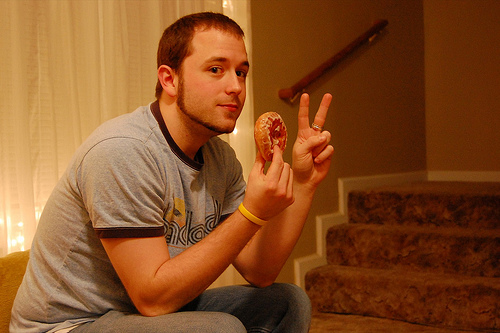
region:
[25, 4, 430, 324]
Man holding a donut.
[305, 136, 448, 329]
Stairs in the background.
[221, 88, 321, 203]
Donut in man's hands.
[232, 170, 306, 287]
Wrist band on man's arm.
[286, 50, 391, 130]
Railing on the wall.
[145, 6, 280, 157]
Man with facial hair.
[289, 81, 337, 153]
Ring on man's finger.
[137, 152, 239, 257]
Design on t-shirt.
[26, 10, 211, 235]
White curtains in the background.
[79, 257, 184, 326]
Denim on the man.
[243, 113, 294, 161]
Frosted donut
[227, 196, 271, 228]
Yellow rubber bracelet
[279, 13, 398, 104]
Wooden stair railing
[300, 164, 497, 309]
Brown patterned ascending stairs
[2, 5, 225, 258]
White curtain over window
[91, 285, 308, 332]
Light blue jeans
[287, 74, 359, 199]
Man's hand in a peace sign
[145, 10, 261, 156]
Man's head with brown hair and a beard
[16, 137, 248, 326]
Light blue shirt with dark blue edges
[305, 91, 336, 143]
Finger with a silver ring on it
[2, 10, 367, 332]
a man eating a doughnut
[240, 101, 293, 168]
the doughnut is brown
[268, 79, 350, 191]
the man is giving the peace sign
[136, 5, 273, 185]
the man has brown hair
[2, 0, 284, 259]
the curtains are white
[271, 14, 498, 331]
a handrail is beside the stairs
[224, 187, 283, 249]
the wristband is yellow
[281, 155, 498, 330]
the stairs are brown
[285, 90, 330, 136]
the finger has a ring on it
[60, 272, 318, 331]
the man is wearing jeans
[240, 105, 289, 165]
donut is brown and glazed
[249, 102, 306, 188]
donut is brown and glazed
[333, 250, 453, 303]
staicase is carpeted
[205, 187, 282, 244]
the band is yellow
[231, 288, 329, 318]
the jeans are grey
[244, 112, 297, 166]
the donut is tasy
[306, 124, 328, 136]
the guy is married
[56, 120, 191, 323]
the shirt is grey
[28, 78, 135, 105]
the curtain is white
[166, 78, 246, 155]
the guy has beard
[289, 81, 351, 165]
he has two fingers up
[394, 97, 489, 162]
the wall is yellow